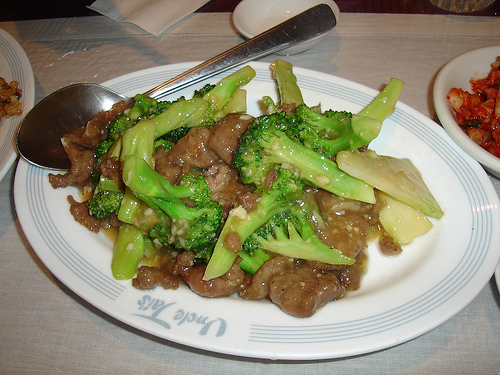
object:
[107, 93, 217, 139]
broccoli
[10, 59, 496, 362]
plate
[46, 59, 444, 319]
food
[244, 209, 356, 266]
broccoli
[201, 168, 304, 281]
broccoli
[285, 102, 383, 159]
broccoli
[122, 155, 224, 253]
broccoli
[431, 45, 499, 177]
plate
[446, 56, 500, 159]
food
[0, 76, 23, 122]
food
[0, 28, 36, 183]
plate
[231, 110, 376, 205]
broccoli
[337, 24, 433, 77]
table